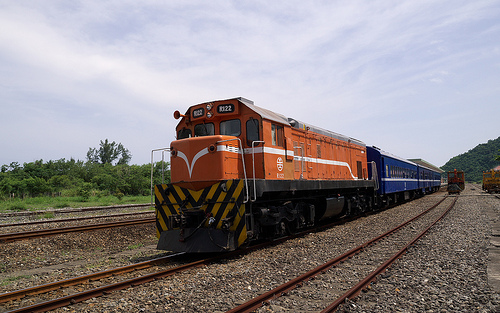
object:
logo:
[276, 157, 285, 171]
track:
[0, 252, 222, 312]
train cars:
[367, 144, 444, 195]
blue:
[366, 145, 440, 196]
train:
[152, 96, 444, 254]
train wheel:
[236, 239, 252, 250]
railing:
[249, 140, 265, 202]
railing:
[216, 138, 248, 204]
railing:
[151, 147, 171, 208]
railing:
[161, 150, 170, 183]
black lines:
[208, 179, 242, 231]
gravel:
[0, 192, 459, 313]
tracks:
[0, 218, 157, 245]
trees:
[0, 159, 23, 170]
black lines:
[154, 184, 180, 226]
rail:
[228, 191, 462, 313]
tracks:
[224, 192, 460, 312]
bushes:
[0, 139, 165, 200]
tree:
[85, 139, 131, 168]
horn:
[173, 110, 186, 120]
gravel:
[340, 185, 497, 313]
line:
[217, 144, 294, 157]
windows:
[245, 116, 261, 148]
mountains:
[441, 134, 500, 184]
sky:
[2, 0, 499, 166]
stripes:
[154, 180, 244, 234]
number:
[218, 105, 232, 112]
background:
[0, 0, 499, 313]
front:
[149, 97, 264, 254]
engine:
[152, 96, 369, 254]